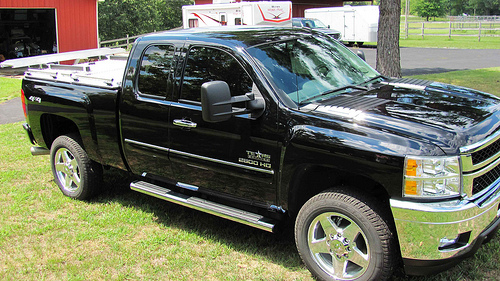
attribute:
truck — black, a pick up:
[50, 42, 412, 238]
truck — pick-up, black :
[29, 23, 410, 279]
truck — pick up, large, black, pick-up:
[20, 13, 480, 278]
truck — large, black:
[33, 41, 474, 278]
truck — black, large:
[34, 50, 484, 258]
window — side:
[146, 48, 165, 101]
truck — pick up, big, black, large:
[10, 19, 483, 261]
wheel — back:
[55, 140, 96, 190]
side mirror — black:
[196, 68, 228, 124]